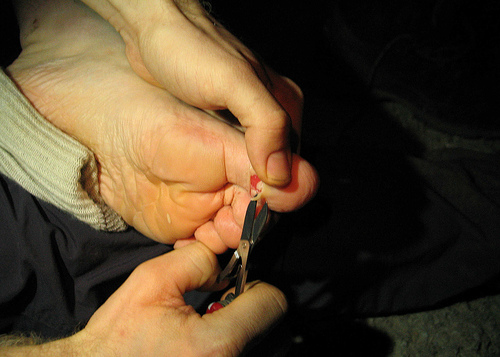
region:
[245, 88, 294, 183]
left-hand thumb holding foot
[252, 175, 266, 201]
nail of big toe being cut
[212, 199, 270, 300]
stainless steel toenail trimmers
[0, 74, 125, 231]
cloth for supporting the foot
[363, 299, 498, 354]
a portion of grey carpet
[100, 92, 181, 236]
heel of left-hand foot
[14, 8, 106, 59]
ankle of left-hand foot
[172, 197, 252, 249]
the other four toes of the foot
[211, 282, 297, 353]
index finger on right hand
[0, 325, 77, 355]
arm hair on right forearm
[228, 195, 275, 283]
small scissors are black and stainless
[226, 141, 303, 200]
toe has a hole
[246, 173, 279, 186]
hole is red on the inside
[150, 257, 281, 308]
hand holding small scissors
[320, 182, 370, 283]
foot on a black sheet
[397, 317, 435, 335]
black sheet on carpet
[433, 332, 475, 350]
carpet is gray and soft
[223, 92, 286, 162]
thumb holding big toe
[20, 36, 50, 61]
foot is white and pale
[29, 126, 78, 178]
heel of foot on sock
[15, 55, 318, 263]
the person's foot being held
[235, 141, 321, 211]
the big toe of the person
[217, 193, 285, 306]
the metal instrument they are holding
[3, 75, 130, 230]
the towel the foot is resting on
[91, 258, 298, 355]
the hand holding the instrument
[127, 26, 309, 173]
the hand holding the toe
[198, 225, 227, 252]
the pinky toe of the foot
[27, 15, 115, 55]
the ankle of the person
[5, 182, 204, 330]
the piece of black canvas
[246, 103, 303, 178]
the person's left hand thumb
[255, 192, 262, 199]
A piece of skin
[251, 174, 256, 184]
A wound in the big toe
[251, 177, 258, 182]
Redness from open skin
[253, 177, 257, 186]
A wound in the big toe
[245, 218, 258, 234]
The blades of a pair of scissors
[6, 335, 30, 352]
Hairs on the arm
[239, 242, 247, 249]
Rivet holding a pair of scissors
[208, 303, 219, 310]
Part of pen knife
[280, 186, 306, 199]
The left big toe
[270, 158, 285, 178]
The nail of a thumb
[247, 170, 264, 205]
Open big toe wound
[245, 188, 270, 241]
Scissors cutting into wound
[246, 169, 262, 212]
Missing skin on wound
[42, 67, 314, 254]
A foot with wound on the toe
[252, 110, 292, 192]
A tumb with finger nail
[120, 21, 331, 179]
A human left hand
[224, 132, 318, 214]
A big toe with skin missing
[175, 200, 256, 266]
Smaller toes compeltely intact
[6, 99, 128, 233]
A white mens sock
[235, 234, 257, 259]
The hinge of a tool